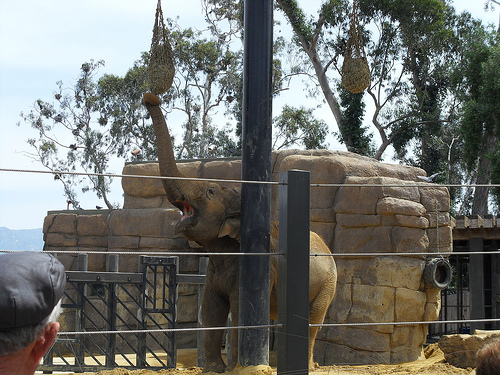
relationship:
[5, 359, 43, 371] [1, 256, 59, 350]
man wearing hat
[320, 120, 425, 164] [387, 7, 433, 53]
tree has foliage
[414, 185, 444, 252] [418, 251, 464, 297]
chain attached to tire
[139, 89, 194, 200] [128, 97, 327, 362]
trunk of elephant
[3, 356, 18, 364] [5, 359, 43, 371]
head of man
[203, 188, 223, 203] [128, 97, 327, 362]
eye of elephant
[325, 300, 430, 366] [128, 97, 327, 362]
rock behind elephant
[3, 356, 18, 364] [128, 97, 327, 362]
head of elephant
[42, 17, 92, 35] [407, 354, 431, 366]
sky above ground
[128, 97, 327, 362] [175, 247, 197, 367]
elephant behind cage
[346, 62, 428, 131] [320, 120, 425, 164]
branches attached to tree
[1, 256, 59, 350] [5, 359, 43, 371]
hat on man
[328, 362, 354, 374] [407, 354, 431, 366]
dirt on ground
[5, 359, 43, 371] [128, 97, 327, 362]
man looking at elephant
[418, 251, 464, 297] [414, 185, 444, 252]
tire on chain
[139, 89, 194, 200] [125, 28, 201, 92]
trunk reaching for feeder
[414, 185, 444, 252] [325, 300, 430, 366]
chain hanging from rock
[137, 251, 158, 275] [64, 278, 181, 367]
rail on bars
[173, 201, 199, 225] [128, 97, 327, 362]
mouth of elephant